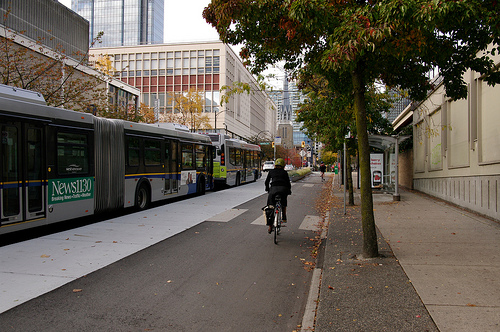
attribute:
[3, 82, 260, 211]
buses — parked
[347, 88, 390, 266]
trunk — brown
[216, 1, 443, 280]
tree — green, small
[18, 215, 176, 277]
sidewalk — white, paved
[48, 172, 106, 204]
billboard — green, white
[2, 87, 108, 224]
bus — long, gray, double, white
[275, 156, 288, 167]
helmet — grey, light colored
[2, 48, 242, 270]
street — black, long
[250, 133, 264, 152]
light — green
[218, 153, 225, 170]
light — red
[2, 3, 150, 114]
building — tan, large, grey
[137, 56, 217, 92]
windows — square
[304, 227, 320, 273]
leaves — brown, dead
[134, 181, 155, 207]
wheel — black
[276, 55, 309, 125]
building — tall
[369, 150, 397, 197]
sign — white, large